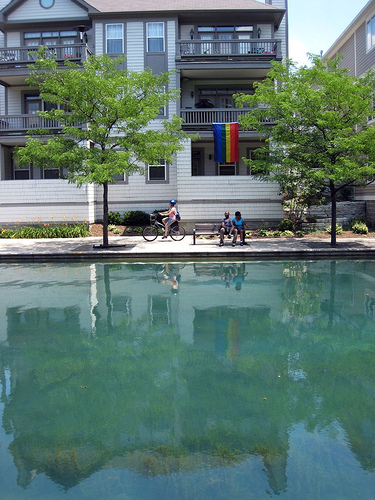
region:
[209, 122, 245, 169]
a rainbow flag hanging off a deck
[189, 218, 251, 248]
a bench beside a pool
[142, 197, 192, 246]
a person riding a bicycle beside a pool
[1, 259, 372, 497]
a building reflected in a pool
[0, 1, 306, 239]
an apartment building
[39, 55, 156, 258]
a green leafy tree by a pool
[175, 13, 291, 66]
a balcony with a wooden railing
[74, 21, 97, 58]
a light on a pole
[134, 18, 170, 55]
a window in a building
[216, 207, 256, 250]
two people on a bench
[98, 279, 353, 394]
this is a swimming pool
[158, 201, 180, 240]
this is a boy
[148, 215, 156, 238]
this is a bicycle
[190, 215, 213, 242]
this is a bench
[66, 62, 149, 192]
this is a tree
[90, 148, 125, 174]
the leavers are green in color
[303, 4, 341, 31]
this is the sky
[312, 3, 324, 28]
the sky is blue in color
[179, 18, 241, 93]
this is a building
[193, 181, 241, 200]
this is the wall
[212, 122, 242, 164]
The rainbow flag hanging from the balcony of the apartment.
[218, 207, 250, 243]
The two people sitting on the bench.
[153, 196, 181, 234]
The person riding the bicycle.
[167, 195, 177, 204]
The blue helmet the person riding the bicycle has on.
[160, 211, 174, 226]
The shorts the person riding the bicycle has on.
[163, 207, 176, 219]
The pink top the person riding the bicycle is wearing.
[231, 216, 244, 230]
The person sitting on the bench with a light blue shirt on.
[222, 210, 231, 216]
The bald head of the person sitting on the left on the bench.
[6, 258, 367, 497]
The water in front of the bench where the people are sitting.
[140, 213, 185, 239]
The bicycle the person is riding on.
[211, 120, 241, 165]
Black, blue, yellow and red flag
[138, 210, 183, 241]
Black bicycle on sidewalk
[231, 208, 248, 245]
Woman wearing blue shirt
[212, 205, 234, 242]
Man sitting next to woman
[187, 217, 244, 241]
Bench couple are sitting on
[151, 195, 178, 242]
Child riding black bicycle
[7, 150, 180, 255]
Tall tree on left in planter in sidewalk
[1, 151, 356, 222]
White house with picture window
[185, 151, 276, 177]
Picture window of white house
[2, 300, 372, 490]
Shadow of trees in the water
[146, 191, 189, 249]
a small by cycle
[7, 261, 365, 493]
beautiful water swimming poll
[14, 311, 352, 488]
shadow reflected in the swimming poll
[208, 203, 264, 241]
two people sitting in the bench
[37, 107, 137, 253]
a large tree on road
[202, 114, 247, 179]
a cloth infront of building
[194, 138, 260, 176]
main door the building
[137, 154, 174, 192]
air conditioner fitted out side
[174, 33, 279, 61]
balcony of the building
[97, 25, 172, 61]
top windows of the building